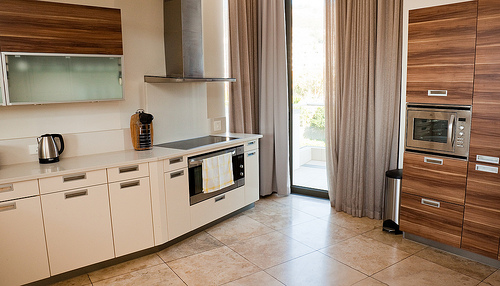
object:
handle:
[420, 197, 440, 209]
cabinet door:
[457, 0, 499, 261]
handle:
[476, 164, 499, 173]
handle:
[0, 202, 18, 213]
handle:
[61, 174, 87, 183]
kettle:
[35, 133, 64, 163]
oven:
[186, 144, 246, 205]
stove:
[152, 135, 238, 150]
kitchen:
[0, 0, 498, 283]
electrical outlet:
[213, 120, 221, 132]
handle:
[52, 135, 65, 154]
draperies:
[316, 0, 400, 220]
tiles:
[162, 242, 274, 279]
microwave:
[404, 102, 471, 157]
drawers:
[394, 188, 471, 250]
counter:
[0, 133, 262, 183]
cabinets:
[0, 50, 125, 105]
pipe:
[143, 0, 241, 84]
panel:
[143, 74, 237, 84]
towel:
[200, 152, 237, 194]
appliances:
[36, 131, 66, 165]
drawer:
[406, 39, 477, 105]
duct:
[143, 0, 240, 85]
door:
[289, 0, 328, 197]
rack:
[130, 109, 155, 151]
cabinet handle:
[423, 157, 441, 165]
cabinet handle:
[427, 88, 447, 96]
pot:
[35, 133, 64, 163]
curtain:
[327, 0, 405, 221]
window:
[284, 0, 328, 197]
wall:
[0, 0, 500, 268]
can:
[382, 169, 403, 236]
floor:
[18, 191, 500, 286]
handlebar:
[189, 149, 237, 165]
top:
[152, 135, 239, 150]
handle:
[63, 189, 88, 199]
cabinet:
[39, 182, 117, 278]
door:
[403, 1, 479, 105]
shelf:
[142, 74, 237, 83]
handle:
[428, 89, 448, 96]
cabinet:
[404, 0, 480, 106]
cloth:
[202, 152, 236, 194]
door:
[185, 143, 244, 206]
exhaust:
[143, 0, 238, 86]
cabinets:
[0, 176, 50, 283]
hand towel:
[199, 151, 234, 194]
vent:
[143, 0, 242, 87]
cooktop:
[154, 131, 263, 161]